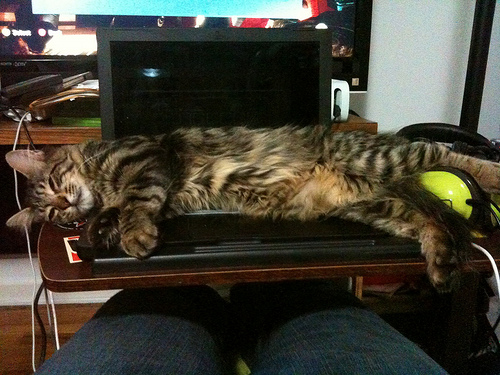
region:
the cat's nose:
[56, 196, 73, 209]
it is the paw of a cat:
[117, 215, 154, 265]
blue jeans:
[106, 310, 246, 367]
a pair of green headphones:
[424, 164, 469, 214]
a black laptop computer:
[179, 218, 337, 258]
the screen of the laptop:
[104, 38, 266, 114]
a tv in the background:
[24, 10, 66, 58]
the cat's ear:
[10, 146, 42, 175]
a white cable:
[477, 240, 499, 273]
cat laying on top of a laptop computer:
[33, 137, 473, 254]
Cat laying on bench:
[2, 125, 497, 265]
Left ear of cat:
[1, 137, 52, 175]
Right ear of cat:
[1, 196, 36, 231]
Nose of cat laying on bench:
[45, 186, 77, 214]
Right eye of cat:
[32, 197, 64, 227]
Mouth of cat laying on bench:
[70, 184, 98, 221]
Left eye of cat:
[41, 161, 71, 192]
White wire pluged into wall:
[5, 100, 43, 373]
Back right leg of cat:
[376, 188, 472, 289]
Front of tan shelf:
[1, 120, 112, 152]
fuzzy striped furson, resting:
[0, 114, 499, 291]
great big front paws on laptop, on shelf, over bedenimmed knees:
[73, 200, 169, 265]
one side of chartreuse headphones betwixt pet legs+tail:
[408, 161, 498, 243]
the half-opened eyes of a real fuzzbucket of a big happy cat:
[43, 175, 60, 221]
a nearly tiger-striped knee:
[321, 128, 444, 186]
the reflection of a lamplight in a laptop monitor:
[138, 57, 171, 87]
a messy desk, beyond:
[0, 57, 374, 134]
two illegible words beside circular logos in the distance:
[0, 22, 71, 41]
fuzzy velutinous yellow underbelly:
[165, 154, 388, 227]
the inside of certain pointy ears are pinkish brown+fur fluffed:
[1, 143, 56, 240]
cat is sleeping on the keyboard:
[24, 135, 422, 241]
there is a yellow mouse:
[416, 171, 470, 225]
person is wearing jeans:
[147, 303, 451, 373]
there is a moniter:
[120, 91, 327, 125]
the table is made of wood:
[49, 266, 389, 300]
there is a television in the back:
[77, 0, 374, 29]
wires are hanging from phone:
[21, 108, 44, 347]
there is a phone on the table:
[1, 76, 53, 98]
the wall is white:
[373, 13, 455, 102]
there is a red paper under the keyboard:
[58, 230, 77, 272]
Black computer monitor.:
[102, 22, 360, 110]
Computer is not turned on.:
[91, 80, 306, 205]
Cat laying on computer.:
[34, 138, 440, 294]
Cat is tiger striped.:
[76, 115, 332, 238]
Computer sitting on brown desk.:
[41, 167, 316, 349]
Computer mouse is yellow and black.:
[414, 138, 489, 299]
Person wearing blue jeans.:
[111, 314, 385, 353]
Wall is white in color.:
[403, 65, 458, 104]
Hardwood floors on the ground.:
[13, 297, 65, 343]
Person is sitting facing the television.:
[26, 20, 251, 185]